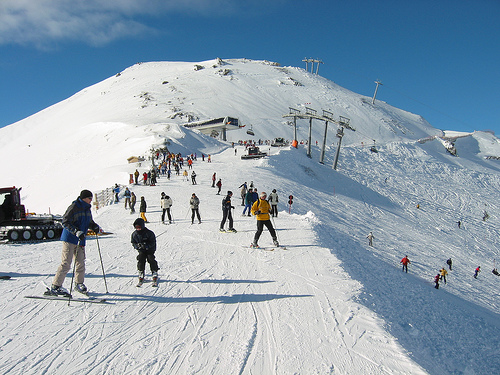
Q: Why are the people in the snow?
A: Skiing.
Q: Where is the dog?
A: No dog.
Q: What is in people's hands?
A: Ski poles.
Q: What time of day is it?
A: Day time.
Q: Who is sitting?
A: No one.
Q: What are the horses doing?
A: No horses.